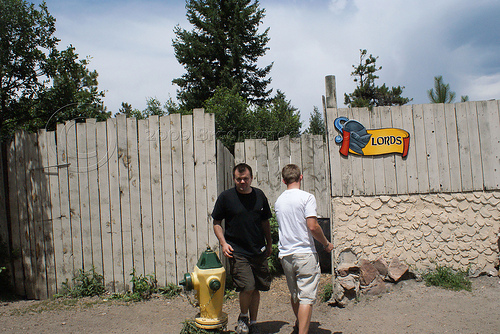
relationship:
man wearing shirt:
[209, 160, 286, 331] [208, 185, 273, 255]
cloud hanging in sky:
[18, 0, 485, 126] [10, 0, 485, 126]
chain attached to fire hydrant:
[182, 286, 216, 310] [178, 243, 234, 332]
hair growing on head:
[230, 160, 254, 180] [230, 160, 253, 192]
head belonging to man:
[230, 160, 253, 192] [209, 160, 286, 331]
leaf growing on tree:
[238, 95, 242, 101] [165, 0, 298, 143]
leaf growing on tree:
[224, 110, 230, 115] [165, 0, 298, 143]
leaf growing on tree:
[227, 104, 231, 110] [165, 0, 298, 143]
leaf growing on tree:
[211, 101, 216, 105] [165, 0, 298, 143]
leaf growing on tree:
[251, 122, 254, 124] [165, 0, 298, 143]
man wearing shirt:
[272, 161, 335, 331] [273, 186, 322, 260]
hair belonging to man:
[230, 160, 254, 180] [209, 160, 286, 331]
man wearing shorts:
[272, 161, 335, 331] [272, 245, 327, 305]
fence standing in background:
[0, 71, 481, 299] [1, 0, 484, 300]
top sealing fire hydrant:
[194, 245, 223, 269] [178, 243, 234, 332]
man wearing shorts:
[209, 160, 286, 331] [216, 235, 281, 296]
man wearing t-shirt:
[272, 161, 335, 331] [271, 187, 321, 260]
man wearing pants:
[272, 161, 335, 331] [280, 251, 321, 303]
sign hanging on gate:
[330, 111, 416, 163] [1, 72, 484, 296]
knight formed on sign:
[331, 112, 372, 157] [330, 111, 416, 163]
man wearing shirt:
[209, 160, 286, 331] [197, 185, 270, 264]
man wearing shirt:
[272, 161, 335, 331] [277, 188, 318, 262]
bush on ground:
[59, 236, 161, 328] [5, 286, 498, 334]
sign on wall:
[330, 111, 416, 163] [321, 101, 496, 201]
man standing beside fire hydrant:
[209, 160, 286, 331] [180, 240, 233, 329]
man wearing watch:
[272, 161, 335, 331] [321, 237, 331, 253]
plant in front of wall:
[411, 253, 482, 297] [317, 84, 498, 300]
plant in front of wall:
[53, 256, 115, 306] [11, 110, 239, 310]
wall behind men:
[9, 73, 497, 285] [215, 155, 337, 332]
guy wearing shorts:
[262, 152, 332, 327] [272, 245, 327, 305]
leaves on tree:
[179, 2, 291, 133] [165, 0, 298, 143]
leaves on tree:
[262, 93, 288, 124] [165, 0, 298, 143]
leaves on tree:
[9, 10, 100, 113] [165, 0, 298, 143]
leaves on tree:
[175, 8, 270, 128] [165, 3, 297, 144]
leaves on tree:
[14, 49, 113, 137] [0, 8, 100, 131]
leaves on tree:
[18, 60, 91, 114] [0, 8, 100, 131]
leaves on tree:
[9, 10, 100, 113] [0, 8, 100, 131]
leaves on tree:
[9, 44, 29, 87] [0, 8, 100, 131]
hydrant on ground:
[180, 240, 233, 330] [0, 246, 500, 332]